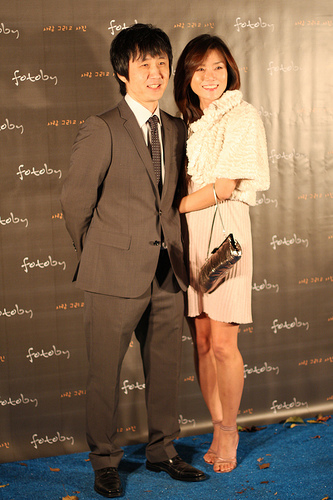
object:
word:
[11, 69, 57, 86]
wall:
[1, 0, 333, 463]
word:
[17, 163, 62, 180]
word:
[234, 17, 274, 32]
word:
[43, 25, 86, 32]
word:
[82, 72, 109, 78]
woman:
[173, 34, 270, 473]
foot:
[214, 428, 237, 473]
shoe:
[213, 424, 238, 473]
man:
[58, 22, 205, 497]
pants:
[84, 257, 184, 473]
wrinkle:
[90, 450, 123, 456]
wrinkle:
[147, 430, 180, 448]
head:
[110, 24, 173, 102]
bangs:
[132, 44, 137, 62]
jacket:
[60, 99, 185, 297]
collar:
[124, 94, 161, 128]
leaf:
[259, 463, 270, 469]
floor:
[0, 415, 332, 499]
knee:
[213, 345, 228, 362]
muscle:
[237, 348, 244, 410]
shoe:
[94, 467, 122, 500]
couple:
[59, 23, 271, 496]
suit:
[61, 99, 187, 468]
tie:
[148, 116, 161, 186]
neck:
[126, 85, 158, 113]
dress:
[184, 90, 270, 323]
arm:
[178, 178, 239, 213]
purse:
[198, 233, 242, 293]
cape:
[186, 89, 270, 208]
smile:
[202, 84, 219, 92]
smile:
[147, 84, 161, 90]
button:
[160, 210, 162, 216]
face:
[190, 57, 228, 99]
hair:
[174, 34, 240, 120]